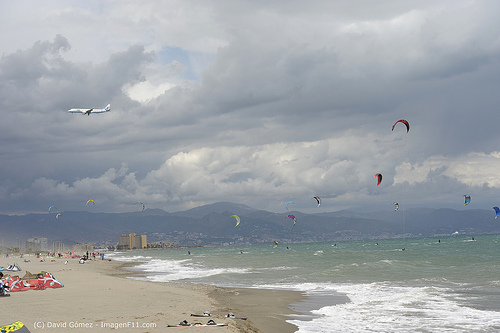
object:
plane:
[66, 98, 109, 123]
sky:
[166, 70, 233, 111]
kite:
[383, 112, 424, 138]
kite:
[370, 161, 403, 205]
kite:
[447, 186, 474, 211]